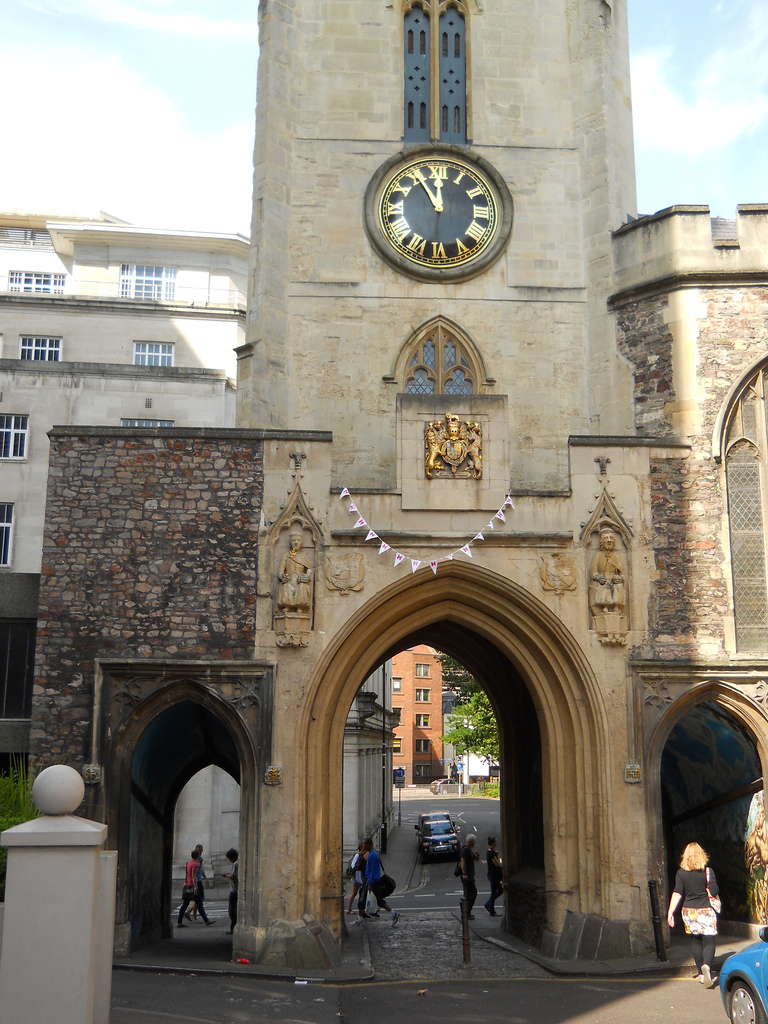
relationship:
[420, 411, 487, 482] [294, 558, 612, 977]
design above arch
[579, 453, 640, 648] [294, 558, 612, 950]
design on right side of arch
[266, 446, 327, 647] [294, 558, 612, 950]
design on left side of arch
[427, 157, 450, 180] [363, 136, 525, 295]
roman numeral on clock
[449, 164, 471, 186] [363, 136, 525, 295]
roman numeral on clock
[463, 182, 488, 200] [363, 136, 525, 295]
roman numeral on clock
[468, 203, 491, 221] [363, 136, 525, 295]
roman numeral on clock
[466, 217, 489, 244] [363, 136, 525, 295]
roman numeral on clock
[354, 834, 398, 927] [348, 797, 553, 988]
person walking on street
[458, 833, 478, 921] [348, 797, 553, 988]
people walking on street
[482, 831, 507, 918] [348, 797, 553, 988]
person walking on street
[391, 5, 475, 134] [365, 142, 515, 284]
window above clock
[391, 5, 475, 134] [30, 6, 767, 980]
window on building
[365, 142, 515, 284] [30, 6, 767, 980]
clock on building